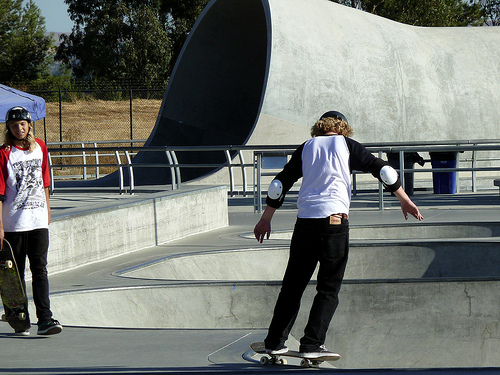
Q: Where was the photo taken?
A: Skatepark.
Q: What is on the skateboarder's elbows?
A: Pads.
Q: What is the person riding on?
A: Skateboard.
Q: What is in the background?
A: Trees.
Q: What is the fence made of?
A: Metal.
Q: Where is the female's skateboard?
A: In right hand.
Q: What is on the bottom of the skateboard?
A: Wheels.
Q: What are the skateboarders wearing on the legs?
A: Black jeans.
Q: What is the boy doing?
A: Skating.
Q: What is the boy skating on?
A: Skateboard.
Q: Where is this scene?
A: Skate park.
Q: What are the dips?
A: Ramps.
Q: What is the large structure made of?
A: Concrete.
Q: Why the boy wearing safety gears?
A: To be safe.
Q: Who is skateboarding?
A: The boy.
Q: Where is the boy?
A: Skateboard rink.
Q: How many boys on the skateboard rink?
A: Two.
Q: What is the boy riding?
A: Skateboard.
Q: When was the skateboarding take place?
A: Daytime.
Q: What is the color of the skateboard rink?
A: Gray.